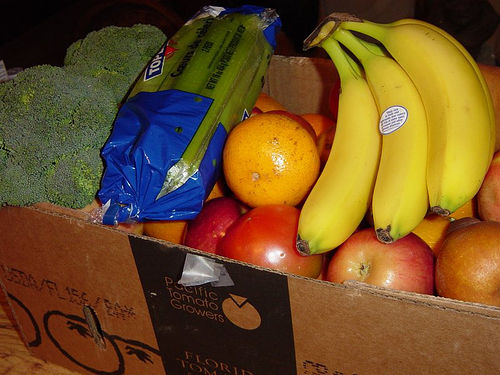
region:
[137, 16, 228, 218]
celery in a bag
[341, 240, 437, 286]
apple in a box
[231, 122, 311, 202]
orange in a box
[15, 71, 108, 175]
broccoli in a box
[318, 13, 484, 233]
bananas in a box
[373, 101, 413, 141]
stickers on a banana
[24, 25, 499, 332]
box with fruit in it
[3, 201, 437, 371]
box on the floor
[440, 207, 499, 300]
pear in a box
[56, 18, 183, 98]
broccoli in a box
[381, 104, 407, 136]
sticker on banana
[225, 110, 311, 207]
an orange in box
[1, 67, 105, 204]
stalk of broccoli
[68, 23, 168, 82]
back stalk of broccoli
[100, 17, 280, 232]
a bag of celery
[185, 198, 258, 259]
red apple in the box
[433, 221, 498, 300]
a pear inside of box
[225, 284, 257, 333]
tomato printed on box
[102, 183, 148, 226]
knot tied in celery bag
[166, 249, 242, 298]
clear tape attached to box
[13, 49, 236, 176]
broccoli is in a box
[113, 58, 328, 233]
celery is in a box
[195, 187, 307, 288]
tomatoes are in a box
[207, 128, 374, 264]
an orange is in a box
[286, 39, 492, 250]
bananas are in a box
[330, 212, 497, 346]
apples are in a box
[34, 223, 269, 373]
the cardboard box has fruit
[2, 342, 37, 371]
the floor is wooden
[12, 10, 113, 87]
the background is dark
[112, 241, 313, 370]
a black patch is on the box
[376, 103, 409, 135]
white fruit sticker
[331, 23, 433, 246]
banana with a fruit sticker on it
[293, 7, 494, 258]
a bunch of yellow bananas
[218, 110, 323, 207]
a round orange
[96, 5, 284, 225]
a bag of celery sticks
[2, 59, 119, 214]
a head of broccoli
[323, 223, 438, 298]
a round red apple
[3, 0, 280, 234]
vegetables in a box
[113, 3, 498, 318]
fruit in a box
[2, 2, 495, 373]
a brown cardboard box full of vegetables and fruit